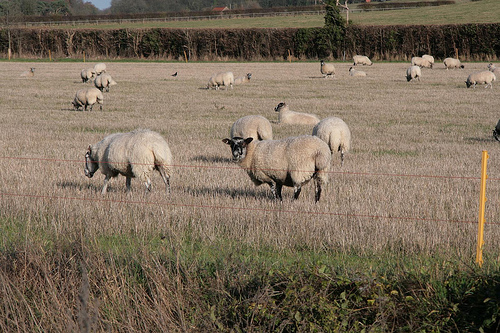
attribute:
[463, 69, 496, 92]
sheep — white